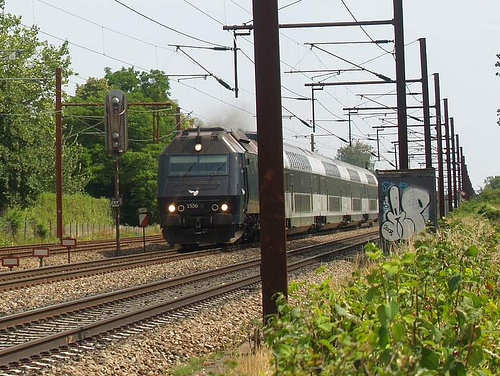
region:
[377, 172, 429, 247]
Graffiti on a metal sign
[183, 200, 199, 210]
Number 1536 on the front of a train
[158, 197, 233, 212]
Headlights on the front of a train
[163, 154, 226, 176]
Windshield glass on the front of a train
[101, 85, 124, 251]
Metal train signal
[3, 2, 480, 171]
Power lines above a train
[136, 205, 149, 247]
Red and white train sign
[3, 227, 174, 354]
Three sets of train tracks on rocky gravel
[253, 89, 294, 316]
Wooden pole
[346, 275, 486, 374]
Green plants growing on the side of a train track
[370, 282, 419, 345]
leaves of a plant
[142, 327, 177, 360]
edge of a railway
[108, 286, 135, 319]
section of a railway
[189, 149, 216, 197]
front part of a rail way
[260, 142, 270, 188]
section of an electric post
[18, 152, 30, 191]
section of a forest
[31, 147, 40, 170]
leaves of a tall tree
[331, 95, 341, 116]
section of power cables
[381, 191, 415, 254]
section of a sign post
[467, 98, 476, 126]
section of the sky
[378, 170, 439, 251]
graffiti is on the wall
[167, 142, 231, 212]
the train has three lights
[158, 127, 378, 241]
the train has many windows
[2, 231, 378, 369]
the tracks are dark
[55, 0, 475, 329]
the poles are made of wood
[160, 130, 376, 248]
the train is silver an black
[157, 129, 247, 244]
the face of the train is black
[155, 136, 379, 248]
the train is on the tracks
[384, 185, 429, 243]
the grafiti is white and black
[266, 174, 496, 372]
the grass is green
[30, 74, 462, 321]
train on train tracks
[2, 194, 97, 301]
three brown and white signs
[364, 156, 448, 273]
one sign with grafitti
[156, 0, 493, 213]
many electrical poles in photo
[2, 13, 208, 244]
green trees in photo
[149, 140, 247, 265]
train nose is black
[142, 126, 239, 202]
one window on train nose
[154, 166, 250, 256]
1556 on train nose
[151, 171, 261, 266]
headlights on train turned on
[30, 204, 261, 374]
several train tracks in photo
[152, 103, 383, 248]
the black color train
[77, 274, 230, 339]
the iron tracks of the railway track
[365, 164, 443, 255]
the signal hordings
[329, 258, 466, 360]
the grass on the side of railway tracks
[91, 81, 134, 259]
the signal hordings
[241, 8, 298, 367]
iron poles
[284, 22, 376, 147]
electrifying wires to run the trains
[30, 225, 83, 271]
the small hordings as signal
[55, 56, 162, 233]
the green trees on the side of the railway track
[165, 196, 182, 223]
the lights of the train